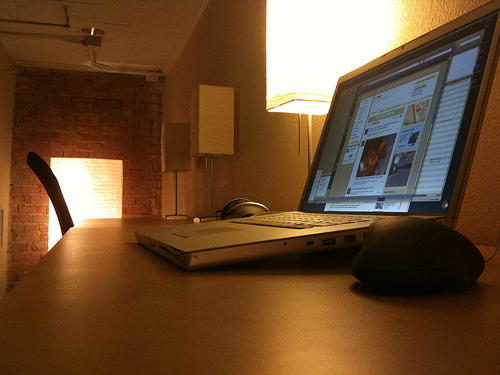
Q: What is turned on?
A: Laptop.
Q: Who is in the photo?
A: No one.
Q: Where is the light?
A: Next to the laptop.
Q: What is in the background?
A: Bricks.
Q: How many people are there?
A: None.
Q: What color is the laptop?
A: Silver.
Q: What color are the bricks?
A: Red.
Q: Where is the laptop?
A: On a counter.